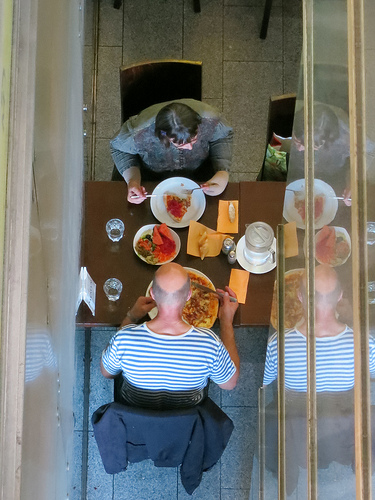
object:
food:
[151, 225, 167, 246]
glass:
[105, 219, 124, 245]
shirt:
[110, 97, 235, 178]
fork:
[181, 184, 207, 196]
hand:
[200, 171, 231, 196]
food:
[164, 191, 194, 223]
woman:
[110, 98, 235, 206]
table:
[84, 180, 287, 327]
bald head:
[152, 258, 190, 295]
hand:
[130, 295, 155, 322]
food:
[158, 222, 176, 242]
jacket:
[91, 395, 237, 498]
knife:
[191, 279, 238, 300]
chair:
[111, 57, 218, 185]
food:
[139, 237, 152, 256]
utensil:
[130, 191, 170, 201]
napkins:
[214, 200, 239, 235]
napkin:
[226, 266, 251, 304]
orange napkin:
[186, 218, 228, 259]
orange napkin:
[281, 219, 299, 260]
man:
[100, 259, 241, 409]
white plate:
[131, 224, 180, 263]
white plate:
[143, 264, 219, 334]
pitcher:
[243, 219, 277, 265]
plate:
[235, 219, 277, 277]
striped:
[115, 336, 218, 354]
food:
[149, 268, 219, 329]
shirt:
[99, 320, 237, 411]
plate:
[149, 176, 206, 228]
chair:
[111, 363, 210, 474]